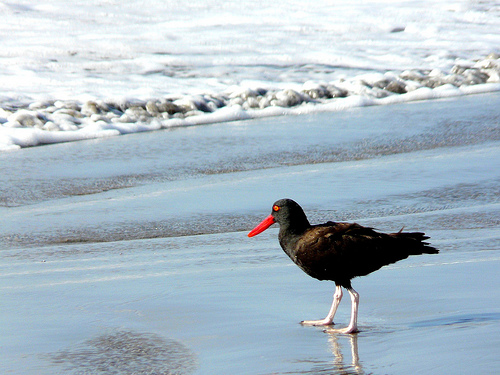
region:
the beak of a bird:
[239, 213, 276, 248]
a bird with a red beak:
[237, 208, 287, 255]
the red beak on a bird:
[223, 212, 280, 262]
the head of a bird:
[242, 180, 313, 248]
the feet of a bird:
[302, 282, 402, 359]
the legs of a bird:
[307, 263, 395, 359]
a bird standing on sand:
[236, 143, 437, 350]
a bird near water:
[51, 0, 434, 310]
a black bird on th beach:
[250, 134, 491, 320]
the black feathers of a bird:
[236, 149, 441, 350]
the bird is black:
[231, 190, 421, 332]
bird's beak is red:
[234, 203, 300, 246]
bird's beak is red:
[239, 183, 300, 269]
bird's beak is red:
[219, 182, 332, 289]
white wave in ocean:
[205, 83, 222, 102]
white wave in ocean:
[257, 56, 282, 79]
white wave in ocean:
[81, 116, 103, 137]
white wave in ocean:
[326, 43, 353, 64]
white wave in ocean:
[396, 79, 425, 104]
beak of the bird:
[240, 215, 275, 239]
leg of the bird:
[341, 303, 366, 341]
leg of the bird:
[308, 297, 336, 324]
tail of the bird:
[398, 228, 448, 268]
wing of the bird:
[326, 243, 355, 273]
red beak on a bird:
[247, 211, 283, 239]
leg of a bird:
[300, 288, 343, 327]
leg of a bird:
[319, 280, 369, 337]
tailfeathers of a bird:
[370, 223, 437, 270]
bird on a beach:
[242, 193, 446, 339]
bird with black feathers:
[242, 178, 449, 338]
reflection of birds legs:
[316, 332, 378, 374]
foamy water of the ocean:
[0, 0, 499, 153]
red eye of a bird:
[272, 202, 282, 214]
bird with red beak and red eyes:
[237, 187, 440, 347]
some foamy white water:
[9, 94, 164, 141]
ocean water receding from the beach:
[40, 72, 391, 181]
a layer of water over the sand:
[46, 236, 253, 351]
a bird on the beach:
[247, 185, 447, 338]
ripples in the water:
[58, 217, 231, 243]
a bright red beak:
[245, 214, 277, 236]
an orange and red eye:
[268, 204, 280, 212]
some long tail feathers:
[388, 224, 437, 261]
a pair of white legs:
[296, 280, 366, 337]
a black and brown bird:
[244, 195, 435, 335]